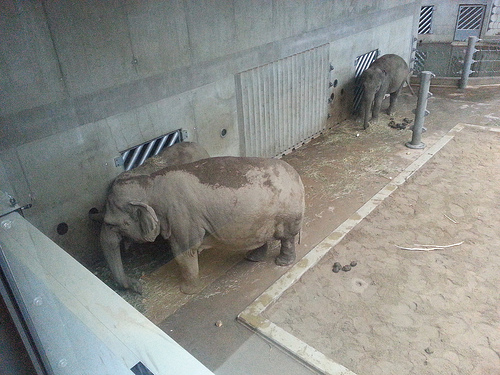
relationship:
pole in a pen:
[404, 71, 435, 149] [2, 7, 485, 367]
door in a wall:
[229, 35, 344, 162] [2, 0, 494, 315]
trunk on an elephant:
[100, 223, 141, 294] [83, 97, 328, 298]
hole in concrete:
[217, 126, 232, 140] [2, 0, 427, 252]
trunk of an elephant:
[100, 223, 141, 294] [112, 162, 307, 287]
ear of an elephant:
[131, 196, 164, 243] [62, 149, 340, 301]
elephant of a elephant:
[97, 156, 304, 294] [93, 150, 312, 294]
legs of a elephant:
[173, 237, 302, 294] [93, 150, 312, 294]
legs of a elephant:
[242, 225, 297, 272] [85, 122, 406, 294]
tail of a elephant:
[297, 225, 302, 245] [93, 150, 312, 294]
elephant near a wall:
[93, 150, 312, 294] [1, 3, 426, 268]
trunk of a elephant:
[358, 87, 376, 131] [361, 54, 416, 129]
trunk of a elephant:
[97, 229, 140, 294] [93, 150, 312, 294]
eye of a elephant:
[100, 223, 123, 236] [100, 155, 305, 296]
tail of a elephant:
[297, 229, 301, 244] [93, 150, 312, 294]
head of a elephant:
[349, 67, 389, 132] [341, 39, 418, 139]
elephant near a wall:
[358, 51, 410, 131] [1, 3, 426, 268]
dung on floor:
[332, 260, 356, 273] [86, 85, 497, 372]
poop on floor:
[386, 115, 413, 129] [86, 85, 497, 372]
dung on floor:
[328, 258, 357, 275] [80, 84, 500, 375]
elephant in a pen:
[97, 156, 304, 294] [2, 7, 485, 367]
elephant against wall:
[93, 150, 312, 294] [1, 3, 426, 268]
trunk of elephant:
[100, 223, 141, 294] [98, 139, 305, 296]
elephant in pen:
[97, 156, 304, 294] [2, 7, 485, 367]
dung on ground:
[332, 260, 356, 273] [55, 84, 498, 368]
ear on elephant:
[129, 201, 160, 243] [79, 150, 316, 274]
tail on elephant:
[402, 67, 417, 108] [354, 49, 419, 129]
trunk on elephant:
[100, 223, 141, 294] [100, 155, 305, 296]